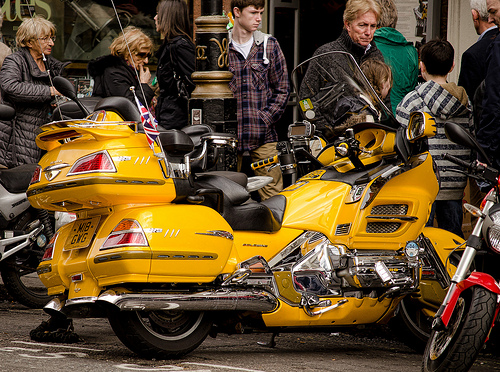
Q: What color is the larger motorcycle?
A: Yellow.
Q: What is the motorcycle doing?
A: It is parked.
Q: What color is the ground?
A: Black.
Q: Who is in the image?
A: Males and females.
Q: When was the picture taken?
A: During the day.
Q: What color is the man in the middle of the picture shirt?
A: Purple.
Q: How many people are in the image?
A: Ten.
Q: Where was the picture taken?
A: In a parking lot.